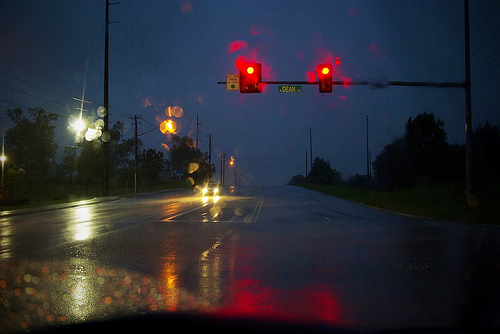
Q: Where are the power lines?
A: Murky distance.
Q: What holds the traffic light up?
A: Metal post.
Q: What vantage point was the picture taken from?
A: Car windshield.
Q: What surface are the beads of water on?
A: Glass windshield.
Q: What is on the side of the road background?
A: Power lines.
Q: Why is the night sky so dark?
A: Rainy weather.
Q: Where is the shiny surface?
A: Road pavement.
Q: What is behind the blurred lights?
A: Line of trees.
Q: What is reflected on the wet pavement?
A: Red traffic lights.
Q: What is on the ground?
A: Rain.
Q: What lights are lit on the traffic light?
A: Red.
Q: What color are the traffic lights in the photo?
A: Red.